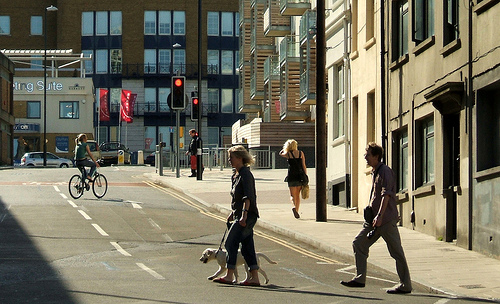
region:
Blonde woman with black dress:
[277, 118, 327, 237]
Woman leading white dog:
[196, 123, 273, 292]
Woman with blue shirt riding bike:
[65, 120, 125, 210]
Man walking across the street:
[335, 116, 435, 302]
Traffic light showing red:
[160, 66, 195, 123]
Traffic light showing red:
[182, 91, 207, 128]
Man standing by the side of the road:
[180, 118, 218, 195]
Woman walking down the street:
[271, 131, 319, 227]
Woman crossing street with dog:
[187, 134, 272, 302]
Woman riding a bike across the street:
[65, 124, 112, 210]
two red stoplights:
[171, 70, 206, 122]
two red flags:
[95, 84, 147, 131]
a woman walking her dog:
[196, 142, 276, 291]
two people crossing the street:
[199, 139, 414, 295]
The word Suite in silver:
[36, 77, 65, 91]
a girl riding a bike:
[70, 130, 108, 200]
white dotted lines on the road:
[47, 177, 170, 284]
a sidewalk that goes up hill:
[180, 161, 487, 296]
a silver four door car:
[19, 149, 72, 171]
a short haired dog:
[198, 243, 272, 283]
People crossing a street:
[193, 135, 449, 302]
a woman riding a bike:
[52, 130, 124, 205]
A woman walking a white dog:
[193, 139, 279, 296]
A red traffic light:
[165, 70, 189, 180]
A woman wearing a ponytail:
[71, 130, 101, 186]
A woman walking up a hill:
[266, 65, 357, 264]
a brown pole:
[306, 26, 343, 223]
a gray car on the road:
[16, 139, 76, 169]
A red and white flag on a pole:
[111, 82, 137, 164]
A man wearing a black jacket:
[183, 126, 205, 187]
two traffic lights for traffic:
[160, 65, 210, 187]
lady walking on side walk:
[271, 132, 338, 241]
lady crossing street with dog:
[174, 145, 291, 302]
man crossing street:
[320, 119, 430, 302]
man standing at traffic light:
[177, 115, 224, 187]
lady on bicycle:
[48, 127, 125, 237]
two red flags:
[80, 66, 145, 166]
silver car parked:
[20, 145, 82, 182]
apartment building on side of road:
[227, 0, 356, 169]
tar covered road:
[10, 155, 379, 302]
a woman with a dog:
[199, 144, 281, 292]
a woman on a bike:
[71, 132, 98, 192]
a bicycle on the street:
[68, 162, 110, 199]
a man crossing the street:
[343, 140, 413, 295]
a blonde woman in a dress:
[277, 130, 314, 226]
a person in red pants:
[183, 125, 201, 180]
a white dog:
[195, 240, 280, 288]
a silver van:
[18, 150, 72, 173]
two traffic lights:
[167, 70, 204, 121]